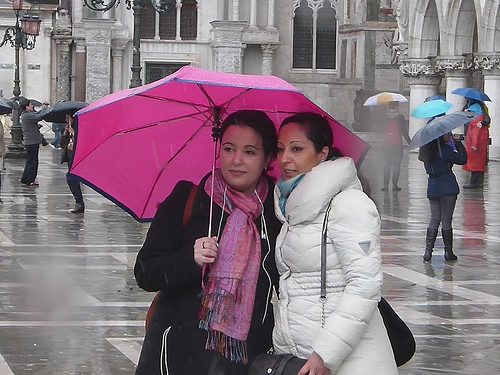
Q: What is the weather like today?
A: It is rainy.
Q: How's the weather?
A: It is rainy.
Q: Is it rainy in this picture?
A: Yes, it is rainy.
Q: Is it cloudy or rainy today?
A: It is rainy.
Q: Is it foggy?
A: No, it is rainy.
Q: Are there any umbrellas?
A: Yes, there is an umbrella.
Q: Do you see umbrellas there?
A: Yes, there is an umbrella.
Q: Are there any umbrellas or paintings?
A: Yes, there is an umbrella.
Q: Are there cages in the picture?
A: No, there are no cages.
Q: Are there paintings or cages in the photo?
A: No, there are no cages or paintings.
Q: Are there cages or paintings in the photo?
A: No, there are no cages or paintings.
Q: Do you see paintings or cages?
A: No, there are no cages or paintings.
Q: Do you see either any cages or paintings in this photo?
A: No, there are no cages or paintings.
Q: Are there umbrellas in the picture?
A: Yes, there is an umbrella.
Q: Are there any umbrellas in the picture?
A: Yes, there is an umbrella.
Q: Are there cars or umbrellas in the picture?
A: Yes, there is an umbrella.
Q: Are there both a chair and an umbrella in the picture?
A: No, there is an umbrella but no chairs.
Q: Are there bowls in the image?
A: No, there are no bowls.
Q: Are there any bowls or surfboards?
A: No, there are no bowls or surfboards.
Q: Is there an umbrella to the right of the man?
A: Yes, there is an umbrella to the right of the man.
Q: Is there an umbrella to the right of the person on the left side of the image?
A: Yes, there is an umbrella to the right of the man.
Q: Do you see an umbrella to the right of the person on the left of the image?
A: Yes, there is an umbrella to the right of the man.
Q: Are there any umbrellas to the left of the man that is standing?
A: No, the umbrella is to the right of the man.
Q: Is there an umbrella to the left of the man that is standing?
A: No, the umbrella is to the right of the man.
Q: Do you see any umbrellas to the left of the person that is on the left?
A: No, the umbrella is to the right of the man.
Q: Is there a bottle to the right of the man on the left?
A: No, there is an umbrella to the right of the man.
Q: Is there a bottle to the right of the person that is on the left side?
A: No, there is an umbrella to the right of the man.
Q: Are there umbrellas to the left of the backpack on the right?
A: Yes, there is an umbrella to the left of the backpack.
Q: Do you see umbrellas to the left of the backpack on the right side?
A: Yes, there is an umbrella to the left of the backpack.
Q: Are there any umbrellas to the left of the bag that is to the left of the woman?
A: Yes, there is an umbrella to the left of the backpack.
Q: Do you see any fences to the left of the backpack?
A: No, there is an umbrella to the left of the backpack.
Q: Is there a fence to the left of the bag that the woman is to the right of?
A: No, there is an umbrella to the left of the backpack.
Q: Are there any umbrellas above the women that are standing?
A: Yes, there is an umbrella above the women.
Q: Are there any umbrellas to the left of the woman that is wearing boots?
A: Yes, there is an umbrella to the left of the woman.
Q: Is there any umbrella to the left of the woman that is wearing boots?
A: Yes, there is an umbrella to the left of the woman.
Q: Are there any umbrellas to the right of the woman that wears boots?
A: No, the umbrella is to the left of the woman.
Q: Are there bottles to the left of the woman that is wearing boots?
A: No, there is an umbrella to the left of the woman.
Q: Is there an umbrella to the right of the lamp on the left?
A: Yes, there is an umbrella to the right of the lamp.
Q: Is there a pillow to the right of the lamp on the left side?
A: No, there is an umbrella to the right of the lamp.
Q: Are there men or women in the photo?
A: Yes, there is a woman.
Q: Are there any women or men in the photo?
A: Yes, there is a woman.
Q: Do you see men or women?
A: Yes, there is a woman.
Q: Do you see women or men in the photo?
A: Yes, there is a woman.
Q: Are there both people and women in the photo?
A: Yes, there are both a woman and a person.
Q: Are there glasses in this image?
A: No, there are no glasses.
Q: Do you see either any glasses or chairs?
A: No, there are no glasses or chairs.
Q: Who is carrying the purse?
A: The woman is carrying the purse.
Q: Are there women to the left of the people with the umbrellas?
A: Yes, there is a woman to the left of the people.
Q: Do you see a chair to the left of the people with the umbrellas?
A: No, there is a woman to the left of the people.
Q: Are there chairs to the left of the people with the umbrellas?
A: No, there is a woman to the left of the people.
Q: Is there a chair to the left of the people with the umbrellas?
A: No, there is a woman to the left of the people.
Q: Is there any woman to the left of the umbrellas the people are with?
A: Yes, there is a woman to the left of the umbrellas.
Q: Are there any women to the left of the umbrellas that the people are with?
A: Yes, there is a woman to the left of the umbrellas.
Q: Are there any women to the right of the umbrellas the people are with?
A: No, the woman is to the left of the umbrellas.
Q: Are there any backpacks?
A: Yes, there is a backpack.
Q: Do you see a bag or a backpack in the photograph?
A: Yes, there is a backpack.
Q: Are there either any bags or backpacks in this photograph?
A: Yes, there is a backpack.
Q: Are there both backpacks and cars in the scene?
A: No, there is a backpack but no cars.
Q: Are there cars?
A: No, there are no cars.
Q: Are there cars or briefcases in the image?
A: No, there are no cars or briefcases.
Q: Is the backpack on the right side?
A: Yes, the backpack is on the right of the image.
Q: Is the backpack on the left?
A: No, the backpack is on the right of the image.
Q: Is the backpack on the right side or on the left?
A: The backpack is on the right of the image.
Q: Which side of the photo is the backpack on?
A: The backpack is on the right of the image.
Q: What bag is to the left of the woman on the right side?
A: The bag is a backpack.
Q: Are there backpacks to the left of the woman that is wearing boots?
A: Yes, there is a backpack to the left of the woman.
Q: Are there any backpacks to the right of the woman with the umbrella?
A: No, the backpack is to the left of the woman.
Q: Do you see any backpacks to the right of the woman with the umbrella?
A: No, the backpack is to the left of the woman.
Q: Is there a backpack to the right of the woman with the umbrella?
A: No, the backpack is to the left of the woman.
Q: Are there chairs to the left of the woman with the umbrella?
A: No, there is a backpack to the left of the woman.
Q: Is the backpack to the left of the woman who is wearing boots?
A: Yes, the backpack is to the left of the woman.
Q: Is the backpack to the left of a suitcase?
A: No, the backpack is to the left of the woman.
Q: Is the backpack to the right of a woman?
A: No, the backpack is to the left of a woman.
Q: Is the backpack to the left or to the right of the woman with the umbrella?
A: The backpack is to the left of the woman.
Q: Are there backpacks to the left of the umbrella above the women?
A: No, the backpack is to the right of the umbrella.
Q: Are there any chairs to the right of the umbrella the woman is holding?
A: No, there is a backpack to the right of the umbrella.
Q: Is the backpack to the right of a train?
A: No, the backpack is to the right of the umbrella.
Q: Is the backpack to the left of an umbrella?
A: No, the backpack is to the right of an umbrella.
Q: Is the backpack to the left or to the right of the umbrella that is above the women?
A: The backpack is to the right of the umbrella.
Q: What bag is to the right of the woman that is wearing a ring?
A: The bag is a backpack.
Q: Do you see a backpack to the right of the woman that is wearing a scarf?
A: Yes, there is a backpack to the right of the woman.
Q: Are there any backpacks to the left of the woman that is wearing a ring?
A: No, the backpack is to the right of the woman.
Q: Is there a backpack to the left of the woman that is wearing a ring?
A: No, the backpack is to the right of the woman.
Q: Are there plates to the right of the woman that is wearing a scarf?
A: No, there is a backpack to the right of the woman.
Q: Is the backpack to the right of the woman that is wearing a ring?
A: Yes, the backpack is to the right of the woman.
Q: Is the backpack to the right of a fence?
A: No, the backpack is to the right of the woman.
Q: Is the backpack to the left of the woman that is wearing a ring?
A: No, the backpack is to the right of the woman.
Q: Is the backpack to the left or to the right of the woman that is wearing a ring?
A: The backpack is to the right of the woman.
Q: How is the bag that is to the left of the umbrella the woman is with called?
A: The bag is a backpack.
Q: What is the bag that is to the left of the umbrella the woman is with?
A: The bag is a backpack.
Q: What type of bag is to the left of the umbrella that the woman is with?
A: The bag is a backpack.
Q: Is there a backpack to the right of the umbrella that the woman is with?
A: No, the backpack is to the left of the umbrella.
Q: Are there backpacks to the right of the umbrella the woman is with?
A: No, the backpack is to the left of the umbrella.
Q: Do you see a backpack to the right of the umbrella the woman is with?
A: No, the backpack is to the left of the umbrella.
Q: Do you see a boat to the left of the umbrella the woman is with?
A: No, there is a backpack to the left of the umbrella.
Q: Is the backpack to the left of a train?
A: No, the backpack is to the left of an umbrella.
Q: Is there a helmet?
A: No, there are no helmets.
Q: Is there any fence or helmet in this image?
A: No, there are no helmets or fences.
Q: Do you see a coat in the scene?
A: Yes, there is a coat.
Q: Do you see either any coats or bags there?
A: Yes, there is a coat.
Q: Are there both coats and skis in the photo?
A: No, there is a coat but no skis.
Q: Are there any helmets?
A: No, there are no helmets.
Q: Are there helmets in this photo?
A: No, there are no helmets.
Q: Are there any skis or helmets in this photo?
A: No, there are no helmets or skis.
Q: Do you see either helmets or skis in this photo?
A: No, there are no helmets or skis.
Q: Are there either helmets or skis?
A: No, there are no helmets or skis.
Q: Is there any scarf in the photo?
A: Yes, there is a scarf.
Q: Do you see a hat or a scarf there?
A: Yes, there is a scarf.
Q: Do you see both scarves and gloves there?
A: No, there is a scarf but no gloves.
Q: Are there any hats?
A: No, there are no hats.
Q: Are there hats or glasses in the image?
A: No, there are no hats or glasses.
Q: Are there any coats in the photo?
A: Yes, there is a coat.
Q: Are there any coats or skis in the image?
A: Yes, there is a coat.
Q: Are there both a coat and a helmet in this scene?
A: No, there is a coat but no helmets.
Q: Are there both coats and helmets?
A: No, there is a coat but no helmets.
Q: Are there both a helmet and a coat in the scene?
A: No, there is a coat but no helmets.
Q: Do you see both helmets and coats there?
A: No, there is a coat but no helmets.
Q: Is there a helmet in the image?
A: No, there are no helmets.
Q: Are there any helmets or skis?
A: No, there are no helmets or skis.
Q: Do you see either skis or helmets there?
A: No, there are no helmets or skis.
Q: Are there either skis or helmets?
A: No, there are no helmets or skis.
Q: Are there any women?
A: Yes, there is a woman.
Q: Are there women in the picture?
A: Yes, there is a woman.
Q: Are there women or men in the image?
A: Yes, there is a woman.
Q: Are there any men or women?
A: Yes, there is a woman.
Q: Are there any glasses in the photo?
A: No, there are no glasses.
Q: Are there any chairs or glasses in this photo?
A: No, there are no glasses or chairs.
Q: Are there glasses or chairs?
A: No, there are no glasses or chairs.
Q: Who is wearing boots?
A: The woman is wearing boots.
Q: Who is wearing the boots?
A: The woman is wearing boots.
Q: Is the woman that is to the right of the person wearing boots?
A: Yes, the woman is wearing boots.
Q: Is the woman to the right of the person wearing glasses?
A: No, the woman is wearing boots.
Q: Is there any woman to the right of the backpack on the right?
A: Yes, there is a woman to the right of the backpack.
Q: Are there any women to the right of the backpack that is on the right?
A: Yes, there is a woman to the right of the backpack.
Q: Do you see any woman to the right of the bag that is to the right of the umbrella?
A: Yes, there is a woman to the right of the backpack.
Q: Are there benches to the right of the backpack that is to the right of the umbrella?
A: No, there is a woman to the right of the backpack.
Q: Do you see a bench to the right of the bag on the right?
A: No, there is a woman to the right of the backpack.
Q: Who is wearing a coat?
A: The woman is wearing a coat.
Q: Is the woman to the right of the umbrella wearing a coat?
A: Yes, the woman is wearing a coat.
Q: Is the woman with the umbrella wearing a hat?
A: No, the woman is wearing a coat.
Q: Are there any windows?
A: Yes, there is a window.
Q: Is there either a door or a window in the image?
A: Yes, there is a window.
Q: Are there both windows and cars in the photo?
A: No, there is a window but no cars.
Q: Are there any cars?
A: No, there are no cars.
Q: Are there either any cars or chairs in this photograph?
A: No, there are no cars or chairs.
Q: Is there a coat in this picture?
A: Yes, there is a coat.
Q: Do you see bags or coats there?
A: Yes, there is a coat.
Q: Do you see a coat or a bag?
A: Yes, there is a coat.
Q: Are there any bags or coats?
A: Yes, there is a coat.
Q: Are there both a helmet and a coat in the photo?
A: No, there is a coat but no helmets.